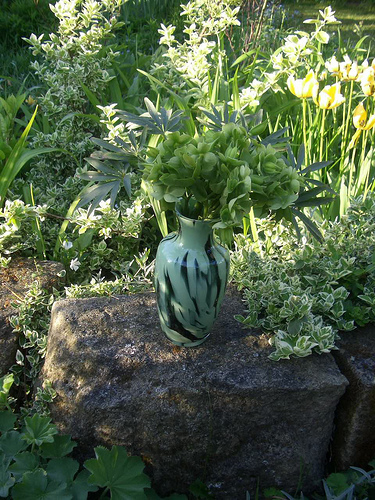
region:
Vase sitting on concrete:
[79, 84, 286, 358]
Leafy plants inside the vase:
[107, 150, 308, 235]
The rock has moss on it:
[102, 379, 276, 493]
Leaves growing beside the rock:
[5, 406, 92, 498]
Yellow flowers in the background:
[282, 56, 374, 123]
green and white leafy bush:
[20, 29, 135, 99]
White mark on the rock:
[197, 458, 230, 492]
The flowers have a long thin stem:
[278, 75, 364, 163]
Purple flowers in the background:
[245, 5, 322, 37]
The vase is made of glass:
[157, 204, 219, 354]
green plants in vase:
[81, 100, 324, 353]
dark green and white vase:
[147, 204, 228, 348]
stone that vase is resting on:
[38, 286, 340, 478]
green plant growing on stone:
[235, 224, 372, 334]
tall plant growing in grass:
[24, 2, 116, 123]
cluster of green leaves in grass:
[1, 409, 147, 498]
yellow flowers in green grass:
[285, 71, 374, 169]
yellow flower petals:
[287, 70, 315, 102]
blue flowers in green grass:
[268, 6, 295, 25]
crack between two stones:
[327, 346, 367, 393]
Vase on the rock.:
[103, 121, 288, 362]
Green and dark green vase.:
[117, 176, 261, 378]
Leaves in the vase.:
[135, 95, 304, 232]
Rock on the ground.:
[35, 275, 333, 495]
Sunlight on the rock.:
[25, 287, 120, 405]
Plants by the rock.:
[20, 414, 110, 498]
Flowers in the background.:
[195, 23, 369, 162]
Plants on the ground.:
[40, 175, 173, 322]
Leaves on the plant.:
[69, 440, 166, 498]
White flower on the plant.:
[50, 230, 93, 285]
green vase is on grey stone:
[145, 207, 243, 357]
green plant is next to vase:
[232, 207, 353, 365]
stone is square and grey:
[43, 320, 304, 473]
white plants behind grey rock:
[35, 12, 217, 213]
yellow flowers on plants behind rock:
[266, 28, 374, 197]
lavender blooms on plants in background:
[237, 4, 304, 57]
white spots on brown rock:
[62, 312, 182, 405]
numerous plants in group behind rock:
[26, 26, 329, 220]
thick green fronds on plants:
[42, 120, 178, 268]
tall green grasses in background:
[0, 27, 29, 119]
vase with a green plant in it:
[122, 128, 300, 360]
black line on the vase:
[176, 249, 209, 314]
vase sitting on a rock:
[50, 201, 326, 498]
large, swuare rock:
[48, 298, 337, 498]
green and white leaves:
[257, 286, 340, 359]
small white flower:
[64, 253, 85, 273]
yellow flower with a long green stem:
[278, 66, 325, 170]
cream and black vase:
[137, 208, 243, 363]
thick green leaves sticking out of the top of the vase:
[126, 115, 304, 255]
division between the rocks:
[332, 353, 365, 461]